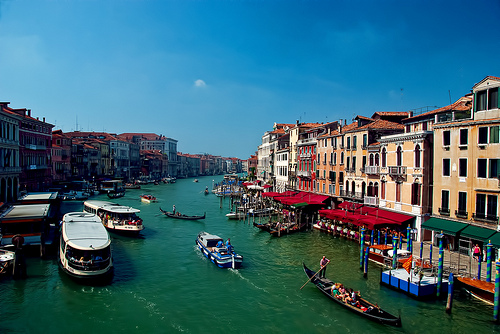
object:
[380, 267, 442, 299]
boat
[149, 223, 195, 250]
water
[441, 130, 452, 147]
window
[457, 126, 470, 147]
window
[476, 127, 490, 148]
window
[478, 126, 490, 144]
window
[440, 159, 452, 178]
window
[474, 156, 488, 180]
window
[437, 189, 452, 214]
window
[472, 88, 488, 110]
window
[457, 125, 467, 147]
window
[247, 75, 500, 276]
building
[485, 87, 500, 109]
window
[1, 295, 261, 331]
water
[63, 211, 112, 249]
top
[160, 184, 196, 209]
water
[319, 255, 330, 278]
man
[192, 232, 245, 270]
boat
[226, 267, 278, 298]
trail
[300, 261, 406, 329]
boat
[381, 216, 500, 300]
dock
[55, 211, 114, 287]
boat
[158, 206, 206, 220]
boat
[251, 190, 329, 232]
dock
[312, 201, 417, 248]
dock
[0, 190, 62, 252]
dock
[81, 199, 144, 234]
boat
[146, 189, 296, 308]
water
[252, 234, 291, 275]
water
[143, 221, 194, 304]
water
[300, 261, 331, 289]
paddle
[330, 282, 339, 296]
people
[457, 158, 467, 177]
window